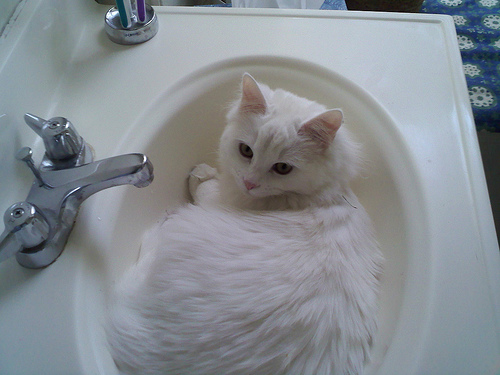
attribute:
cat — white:
[106, 66, 408, 375]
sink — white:
[9, 6, 497, 375]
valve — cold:
[15, 103, 86, 159]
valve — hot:
[1, 195, 59, 270]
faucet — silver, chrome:
[54, 148, 158, 202]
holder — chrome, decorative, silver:
[96, 4, 162, 46]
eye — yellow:
[236, 135, 300, 180]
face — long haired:
[209, 95, 325, 210]